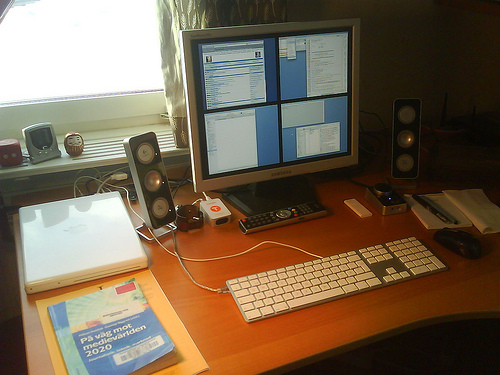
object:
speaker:
[123, 130, 177, 229]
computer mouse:
[433, 225, 483, 259]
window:
[278, 29, 348, 100]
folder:
[36, 267, 209, 375]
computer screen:
[193, 27, 352, 178]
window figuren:
[0, 137, 23, 166]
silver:
[371, 261, 388, 273]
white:
[272, 270, 313, 292]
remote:
[236, 201, 329, 235]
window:
[202, 100, 281, 175]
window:
[193, 31, 278, 111]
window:
[278, 93, 351, 164]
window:
[0, 0, 190, 135]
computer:
[174, 17, 364, 217]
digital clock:
[21, 121, 62, 165]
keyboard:
[224, 236, 448, 321]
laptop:
[19, 191, 147, 296]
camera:
[365, 184, 408, 217]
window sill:
[0, 119, 170, 171]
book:
[47, 278, 184, 374]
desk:
[13, 166, 498, 373]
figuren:
[63, 132, 85, 156]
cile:
[1, 120, 177, 188]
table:
[13, 167, 500, 375]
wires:
[87, 177, 322, 262]